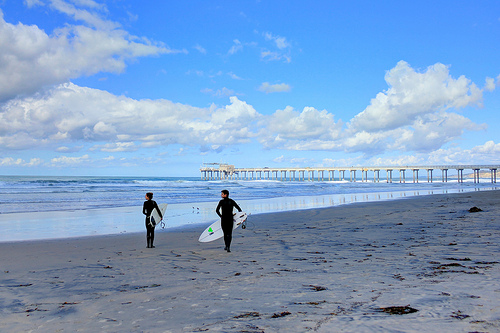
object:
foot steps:
[158, 249, 212, 279]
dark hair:
[221, 189, 230, 197]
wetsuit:
[216, 198, 242, 253]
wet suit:
[143, 200, 164, 248]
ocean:
[0, 175, 500, 242]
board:
[149, 202, 168, 227]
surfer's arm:
[153, 202, 163, 219]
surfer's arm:
[143, 202, 147, 215]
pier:
[198, 164, 500, 187]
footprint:
[232, 270, 242, 280]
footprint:
[170, 262, 183, 269]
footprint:
[270, 306, 291, 319]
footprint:
[235, 310, 255, 317]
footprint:
[294, 253, 306, 265]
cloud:
[2, 58, 266, 151]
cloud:
[1, 7, 180, 101]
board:
[198, 212, 247, 243]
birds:
[192, 206, 200, 214]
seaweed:
[379, 305, 417, 314]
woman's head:
[145, 192, 153, 200]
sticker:
[208, 226, 213, 232]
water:
[10, 168, 289, 213]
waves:
[249, 179, 284, 185]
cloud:
[339, 58, 479, 158]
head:
[220, 190, 229, 199]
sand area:
[316, 217, 387, 322]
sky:
[0, 2, 498, 183]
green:
[208, 227, 214, 232]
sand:
[0, 188, 498, 330]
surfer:
[142, 192, 163, 248]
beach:
[2, 185, 484, 332]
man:
[215, 189, 244, 253]